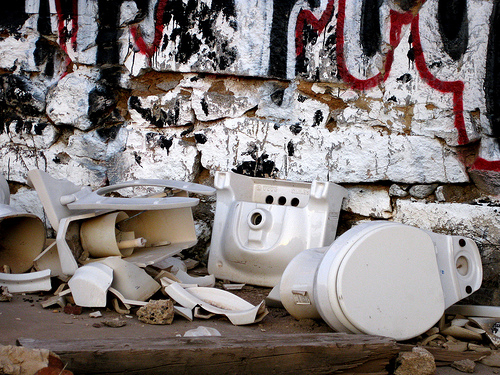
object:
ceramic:
[0, 170, 484, 340]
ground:
[0, 302, 500, 375]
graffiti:
[0, 0, 500, 186]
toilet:
[0, 0, 500, 375]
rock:
[136, 298, 174, 324]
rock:
[392, 346, 436, 374]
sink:
[207, 169, 349, 288]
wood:
[15, 333, 401, 375]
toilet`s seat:
[328, 222, 445, 341]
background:
[1, 0, 499, 273]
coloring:
[410, 14, 427, 67]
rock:
[92, 320, 127, 328]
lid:
[336, 224, 446, 341]